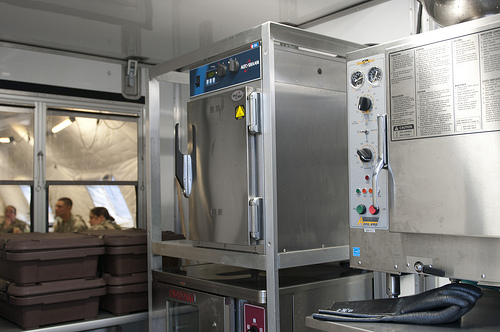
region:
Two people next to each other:
[51, 197, 110, 229]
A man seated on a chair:
[52, 196, 84, 231]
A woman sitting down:
[87, 205, 114, 229]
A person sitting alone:
[1, 204, 26, 231]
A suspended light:
[57, 124, 64, 128]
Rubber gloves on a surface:
[361, 297, 459, 317]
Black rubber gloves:
[357, 299, 456, 319]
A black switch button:
[360, 97, 370, 109]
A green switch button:
[355, 204, 364, 212]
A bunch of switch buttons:
[354, 187, 371, 194]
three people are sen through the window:
[3, 184, 120, 236]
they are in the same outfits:
[8, 189, 125, 226]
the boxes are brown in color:
[22, 229, 147, 309]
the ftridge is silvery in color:
[210, 69, 352, 269]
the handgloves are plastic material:
[331, 286, 477, 325]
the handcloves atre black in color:
[350, 267, 460, 320]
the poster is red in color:
[226, 297, 268, 329]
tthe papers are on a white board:
[399, 62, 499, 146]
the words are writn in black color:
[404, 66, 498, 113]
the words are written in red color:
[163, 284, 208, 310]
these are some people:
[7, 199, 119, 227]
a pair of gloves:
[312, 284, 489, 324]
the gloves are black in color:
[361, 299, 390, 307]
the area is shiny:
[212, 161, 247, 202]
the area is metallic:
[202, 146, 247, 201]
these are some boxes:
[25, 234, 120, 319]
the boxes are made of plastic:
[53, 239, 95, 308]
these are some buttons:
[342, 174, 388, 219]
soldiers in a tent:
[2, 193, 114, 245]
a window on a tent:
[83, 175, 133, 228]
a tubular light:
[48, 116, 78, 136]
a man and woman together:
[50, 190, 114, 228]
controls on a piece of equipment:
[339, 60, 385, 222]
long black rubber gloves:
[318, 276, 487, 328]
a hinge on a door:
[242, 87, 264, 134]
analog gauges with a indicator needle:
[365, 65, 385, 85]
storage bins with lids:
[5, 220, 115, 325]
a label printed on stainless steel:
[385, 44, 499, 136]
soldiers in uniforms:
[0, 198, 125, 233]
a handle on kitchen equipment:
[169, 117, 196, 195]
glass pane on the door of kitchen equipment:
[156, 295, 202, 330]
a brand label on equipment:
[159, 283, 199, 306]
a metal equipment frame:
[255, 20, 294, 323]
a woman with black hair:
[87, 204, 117, 228]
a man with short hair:
[52, 196, 73, 221]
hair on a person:
[93, 203, 120, 223]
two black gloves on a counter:
[312, 270, 479, 328]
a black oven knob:
[355, 95, 371, 113]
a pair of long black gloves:
[313, 278, 483, 330]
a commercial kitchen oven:
[136, 16, 351, 253]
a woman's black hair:
[90, 201, 115, 221]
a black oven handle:
[170, 120, 190, 190]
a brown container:
[0, 230, 105, 280]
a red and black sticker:
[230, 105, 240, 120]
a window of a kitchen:
[46, 106, 136, 226]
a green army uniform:
[50, 211, 86, 227]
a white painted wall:
[2, 47, 122, 93]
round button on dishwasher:
[366, 203, 376, 216]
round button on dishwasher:
[361, 186, 366, 194]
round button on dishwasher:
[363, 171, 369, 183]